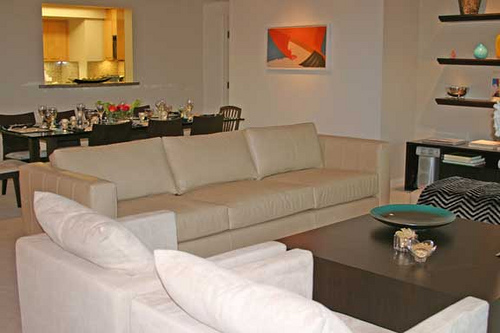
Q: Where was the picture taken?
A: In a house.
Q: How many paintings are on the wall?
A: One.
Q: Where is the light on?
A: In the kitchen.